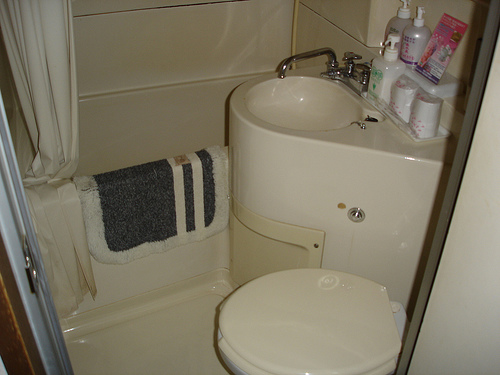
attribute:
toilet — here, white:
[201, 265, 409, 372]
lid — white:
[214, 266, 404, 369]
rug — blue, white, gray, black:
[78, 147, 224, 265]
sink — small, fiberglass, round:
[229, 61, 438, 302]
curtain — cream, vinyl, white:
[2, 3, 103, 318]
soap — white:
[370, 57, 401, 107]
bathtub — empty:
[4, 69, 267, 332]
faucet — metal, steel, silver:
[275, 48, 371, 94]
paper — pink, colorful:
[417, 4, 467, 88]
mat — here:
[77, 147, 226, 262]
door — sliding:
[0, 88, 75, 375]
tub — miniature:
[6, 75, 285, 334]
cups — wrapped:
[390, 77, 443, 138]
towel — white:
[27, 189, 101, 324]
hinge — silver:
[18, 238, 45, 299]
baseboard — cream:
[60, 274, 230, 374]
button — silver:
[350, 208, 364, 223]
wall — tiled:
[67, 1, 291, 96]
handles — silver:
[342, 48, 373, 90]